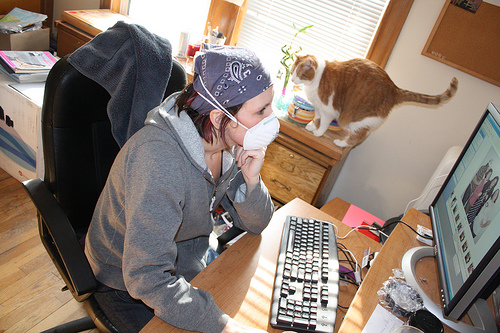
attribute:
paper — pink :
[340, 197, 390, 244]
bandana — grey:
[196, 48, 268, 105]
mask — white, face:
[202, 81, 323, 179]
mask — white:
[194, 72, 281, 152]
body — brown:
[317, 60, 395, 125]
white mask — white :
[192, 66, 278, 157]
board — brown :
[424, 6, 499, 74]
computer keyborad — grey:
[267, 214, 339, 331]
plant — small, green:
[280, 20, 313, 94]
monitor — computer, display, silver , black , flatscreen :
[425, 100, 499, 322]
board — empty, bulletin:
[417, 2, 487, 99]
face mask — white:
[195, 75, 280, 152]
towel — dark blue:
[59, 25, 159, 103]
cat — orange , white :
[288, 43, 406, 141]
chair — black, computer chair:
[24, 52, 185, 330]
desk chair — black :
[41, 18, 189, 330]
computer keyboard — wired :
[262, 211, 346, 328]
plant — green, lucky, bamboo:
[269, 14, 318, 116]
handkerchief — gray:
[183, 39, 282, 114]